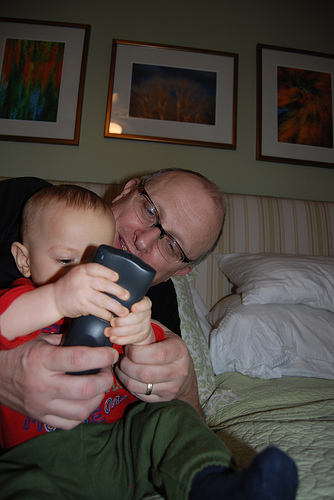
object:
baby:
[0, 181, 296, 500]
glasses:
[132, 182, 191, 263]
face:
[113, 164, 219, 290]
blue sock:
[189, 446, 296, 500]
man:
[0, 165, 228, 432]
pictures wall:
[0, 0, 334, 200]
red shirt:
[0, 277, 166, 452]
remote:
[58, 241, 154, 376]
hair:
[24, 183, 113, 235]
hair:
[143, 166, 227, 275]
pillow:
[214, 250, 332, 311]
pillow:
[209, 303, 333, 380]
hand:
[103, 294, 152, 343]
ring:
[145, 384, 154, 395]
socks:
[187, 446, 298, 499]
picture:
[255, 41, 333, 170]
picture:
[103, 38, 238, 152]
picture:
[0, 15, 90, 145]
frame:
[256, 42, 334, 168]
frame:
[102, 37, 236, 150]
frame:
[0, 16, 91, 146]